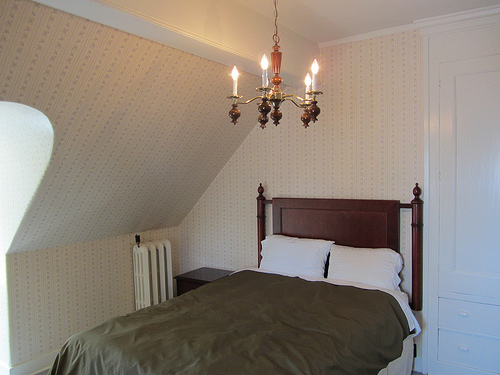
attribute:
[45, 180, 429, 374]
bed — brown, wooden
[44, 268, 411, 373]
blanket — green, brown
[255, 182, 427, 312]
headboard — brown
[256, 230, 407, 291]
pillows — white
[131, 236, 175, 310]
radiator — white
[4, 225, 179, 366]
wall — white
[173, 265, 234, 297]
nightstand — brown, wood, wooden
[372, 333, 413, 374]
bedskirt — white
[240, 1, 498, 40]
ceiling — white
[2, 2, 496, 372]
bedroom — pastel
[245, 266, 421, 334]
sheet — white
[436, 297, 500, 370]
drawers — white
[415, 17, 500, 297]
door — white